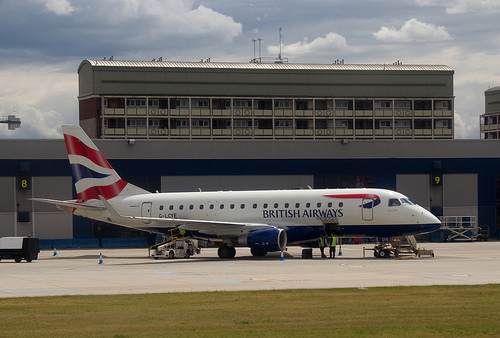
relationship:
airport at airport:
[0, 48, 499, 337] [65, 48, 453, 173]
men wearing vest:
[313, 232, 338, 263] [316, 236, 337, 248]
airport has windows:
[0, 48, 499, 337] [154, 201, 359, 219]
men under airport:
[313, 232, 338, 263] [0, 48, 499, 337]